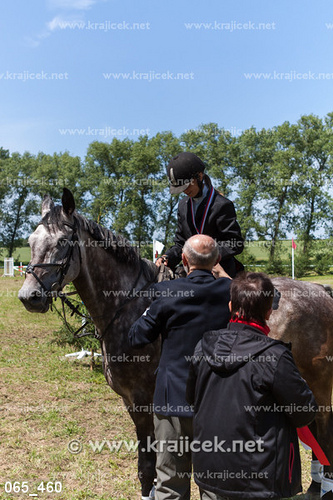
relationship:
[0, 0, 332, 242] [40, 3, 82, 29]
sky has clouds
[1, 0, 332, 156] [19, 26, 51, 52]
sky has cloud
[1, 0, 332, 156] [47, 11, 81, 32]
sky has cloud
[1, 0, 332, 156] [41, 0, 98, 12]
sky has cloud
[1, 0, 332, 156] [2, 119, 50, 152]
sky has cloud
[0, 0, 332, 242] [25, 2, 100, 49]
sky has clouds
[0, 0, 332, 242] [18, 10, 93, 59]
sky has clouds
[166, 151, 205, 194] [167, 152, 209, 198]
hat on head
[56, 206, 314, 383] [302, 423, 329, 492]
horse with leg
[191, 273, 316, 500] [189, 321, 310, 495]
man in jacket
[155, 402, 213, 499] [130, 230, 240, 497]
pants on man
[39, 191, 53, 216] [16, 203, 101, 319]
ear on head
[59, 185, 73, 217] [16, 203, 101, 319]
ear on head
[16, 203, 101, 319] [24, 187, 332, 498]
head of horse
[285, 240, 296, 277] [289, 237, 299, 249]
pole with flag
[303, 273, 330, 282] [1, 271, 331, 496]
grass on ground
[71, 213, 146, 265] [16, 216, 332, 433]
mane on horse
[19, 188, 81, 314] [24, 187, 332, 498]
head of horse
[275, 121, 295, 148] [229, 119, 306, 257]
leaves on tree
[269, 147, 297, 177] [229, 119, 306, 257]
leaves on tree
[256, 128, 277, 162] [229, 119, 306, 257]
leaves on tree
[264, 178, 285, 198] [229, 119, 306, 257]
leaves on tree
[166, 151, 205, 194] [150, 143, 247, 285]
hat on jockey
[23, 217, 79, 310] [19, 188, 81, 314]
bridle on head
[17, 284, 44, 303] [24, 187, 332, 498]
nose of horse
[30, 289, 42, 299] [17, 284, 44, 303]
nostrils on nose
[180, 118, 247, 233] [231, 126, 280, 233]
tree with leaves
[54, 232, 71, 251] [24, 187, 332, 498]
eye of horse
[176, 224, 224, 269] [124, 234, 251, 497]
head of man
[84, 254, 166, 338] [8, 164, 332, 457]
reins on horse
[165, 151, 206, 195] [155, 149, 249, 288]
hat on top of jockey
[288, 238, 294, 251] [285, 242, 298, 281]
flag on pole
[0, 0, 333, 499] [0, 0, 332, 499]
water mark on a photo